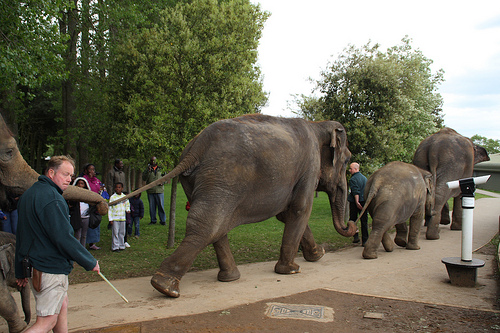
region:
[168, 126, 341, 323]
the elephants are visible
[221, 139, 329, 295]
the elephants are visible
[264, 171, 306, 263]
the elephants are visible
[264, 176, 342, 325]
the elephants are visible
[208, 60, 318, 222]
the elephants are visible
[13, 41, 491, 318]
a herd of elephants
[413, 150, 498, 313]
this pole is white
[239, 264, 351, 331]
there is an electric box cover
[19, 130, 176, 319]
a man walking beside elephants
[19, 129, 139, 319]
he has on shorts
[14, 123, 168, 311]
the man's sweater is blue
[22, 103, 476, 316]
there are four elephants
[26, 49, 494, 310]
these are asian elephants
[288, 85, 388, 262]
mother and child elephants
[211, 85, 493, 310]
the elephants hold tails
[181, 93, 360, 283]
gray animal walking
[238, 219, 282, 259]
grass next to elephant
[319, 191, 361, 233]
trunk on the elephant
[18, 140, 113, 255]
man behind the elephant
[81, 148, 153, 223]
people next to the elephants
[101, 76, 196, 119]
trees behind the people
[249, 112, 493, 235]
three elephants in a row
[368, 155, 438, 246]
smaller elephant in middle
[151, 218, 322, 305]
legs of the elephant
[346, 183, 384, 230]
tail of the elephant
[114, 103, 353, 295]
a walking grey elephant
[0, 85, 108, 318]
a walking grey elephant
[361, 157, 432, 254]
a walking grey elephant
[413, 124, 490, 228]
a walking grey elephant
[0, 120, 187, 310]
elephant trunk holding tail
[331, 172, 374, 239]
elephant trunk holding tail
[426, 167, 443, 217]
elephant trunk holding tail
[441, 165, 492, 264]
a white telescope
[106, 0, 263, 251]
a tall green tree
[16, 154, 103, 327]
a man walking on sidewalk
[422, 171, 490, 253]
white post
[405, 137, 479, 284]
white post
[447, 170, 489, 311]
white post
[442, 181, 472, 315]
white post